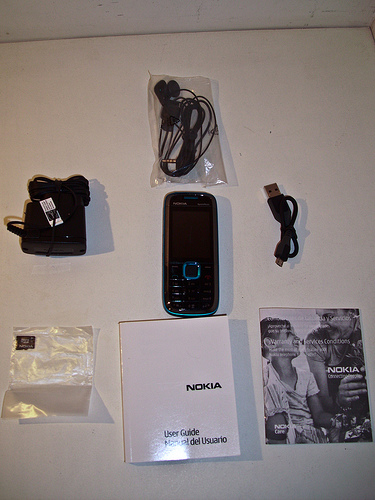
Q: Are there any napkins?
A: No, there are no napkins.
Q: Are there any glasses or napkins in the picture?
A: No, there are no napkins or glasses.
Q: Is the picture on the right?
A: Yes, the picture is on the right of the image.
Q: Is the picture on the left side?
A: No, the picture is on the right of the image.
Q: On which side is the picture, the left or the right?
A: The picture is on the right of the image.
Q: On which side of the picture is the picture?
A: The picture is on the right of the image.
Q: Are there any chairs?
A: No, there are no chairs.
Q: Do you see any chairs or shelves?
A: No, there are no chairs or shelves.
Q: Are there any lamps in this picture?
A: No, there are no lamps.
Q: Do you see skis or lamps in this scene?
A: No, there are no lamps or skis.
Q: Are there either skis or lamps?
A: No, there are no lamps or skis.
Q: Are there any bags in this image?
A: Yes, there is a bag.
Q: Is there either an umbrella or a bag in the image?
A: Yes, there is a bag.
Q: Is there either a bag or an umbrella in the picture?
A: Yes, there is a bag.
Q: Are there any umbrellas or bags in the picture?
A: Yes, there is a bag.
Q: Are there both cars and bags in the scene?
A: No, there is a bag but no cars.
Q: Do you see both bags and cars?
A: No, there is a bag but no cars.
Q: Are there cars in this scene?
A: No, there are no cars.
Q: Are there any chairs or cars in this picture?
A: No, there are no cars or chairs.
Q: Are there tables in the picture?
A: Yes, there is a table.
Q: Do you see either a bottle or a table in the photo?
A: Yes, there is a table.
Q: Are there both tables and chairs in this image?
A: No, there is a table but no chairs.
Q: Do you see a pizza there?
A: No, there are no pizzas.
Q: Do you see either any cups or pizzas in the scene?
A: No, there are no pizzas or cups.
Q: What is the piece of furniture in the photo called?
A: The piece of furniture is a table.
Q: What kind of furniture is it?
A: The piece of furniture is a table.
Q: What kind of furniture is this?
A: This is a table.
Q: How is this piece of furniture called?
A: This is a table.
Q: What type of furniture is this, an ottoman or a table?
A: This is a table.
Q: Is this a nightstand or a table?
A: This is a table.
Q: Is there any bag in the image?
A: Yes, there is a bag.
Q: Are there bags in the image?
A: Yes, there is a bag.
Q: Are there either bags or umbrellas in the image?
A: Yes, there is a bag.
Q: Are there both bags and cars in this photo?
A: No, there is a bag but no cars.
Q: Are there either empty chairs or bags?
A: Yes, there is an empty bag.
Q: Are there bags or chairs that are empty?
A: Yes, the bag is empty.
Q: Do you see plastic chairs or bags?
A: Yes, there is a plastic bag.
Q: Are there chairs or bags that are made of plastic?
A: Yes, the bag is made of plastic.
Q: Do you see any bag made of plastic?
A: Yes, there is a bag that is made of plastic.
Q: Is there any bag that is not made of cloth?
A: Yes, there is a bag that is made of plastic.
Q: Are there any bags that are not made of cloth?
A: Yes, there is a bag that is made of plastic.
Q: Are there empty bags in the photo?
A: Yes, there is an empty bag.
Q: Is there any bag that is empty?
A: Yes, there is an empty bag.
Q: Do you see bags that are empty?
A: Yes, there is an empty bag.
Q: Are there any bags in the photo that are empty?
A: Yes, there is a bag that is empty.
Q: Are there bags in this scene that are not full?
A: Yes, there is a empty bag.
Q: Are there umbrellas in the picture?
A: No, there are no umbrellas.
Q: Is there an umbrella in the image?
A: No, there are no umbrellas.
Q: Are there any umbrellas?
A: No, there are no umbrellas.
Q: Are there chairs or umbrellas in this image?
A: No, there are no umbrellas or chairs.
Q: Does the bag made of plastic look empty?
A: Yes, the bag is empty.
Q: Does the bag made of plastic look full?
A: No, the bag is empty.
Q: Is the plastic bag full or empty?
A: The bag is empty.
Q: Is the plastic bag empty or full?
A: The bag is empty.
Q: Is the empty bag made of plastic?
A: Yes, the bag is made of plastic.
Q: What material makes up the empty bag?
A: The bag is made of plastic.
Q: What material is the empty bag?
A: The bag is made of plastic.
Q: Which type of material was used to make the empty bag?
A: The bag is made of plastic.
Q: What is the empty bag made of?
A: The bag is made of plastic.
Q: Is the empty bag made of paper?
A: No, the bag is made of plastic.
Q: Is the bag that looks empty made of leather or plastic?
A: The bag is made of plastic.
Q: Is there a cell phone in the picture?
A: Yes, there is a cell phone.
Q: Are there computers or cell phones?
A: Yes, there is a cell phone.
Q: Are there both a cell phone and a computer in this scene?
A: No, there is a cell phone but no computers.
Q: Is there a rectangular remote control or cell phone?
A: Yes, there is a rectangular cell phone.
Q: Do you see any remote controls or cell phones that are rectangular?
A: Yes, the cell phone is rectangular.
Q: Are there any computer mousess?
A: No, there are no computer mousess.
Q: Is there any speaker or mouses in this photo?
A: No, there are no computer mousess or speakers.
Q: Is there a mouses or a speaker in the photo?
A: No, there are no computer mousess or speakers.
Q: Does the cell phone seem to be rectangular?
A: Yes, the cell phone is rectangular.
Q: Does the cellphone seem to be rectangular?
A: Yes, the cellphone is rectangular.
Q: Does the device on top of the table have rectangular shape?
A: Yes, the cellphone is rectangular.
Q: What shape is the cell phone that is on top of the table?
A: The cellphone is rectangular.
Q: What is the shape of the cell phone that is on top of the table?
A: The cellphone is rectangular.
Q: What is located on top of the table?
A: The cell phone is on top of the table.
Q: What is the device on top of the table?
A: The device is a cell phone.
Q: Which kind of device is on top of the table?
A: The device is a cell phone.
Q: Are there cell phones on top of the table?
A: Yes, there is a cell phone on top of the table.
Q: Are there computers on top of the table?
A: No, there is a cell phone on top of the table.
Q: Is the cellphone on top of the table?
A: Yes, the cellphone is on top of the table.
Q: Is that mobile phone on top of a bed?
A: No, the mobile phone is on top of the table.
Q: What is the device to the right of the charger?
A: The device is a cell phone.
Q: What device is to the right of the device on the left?
A: The device is a cell phone.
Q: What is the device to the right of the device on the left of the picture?
A: The device is a cell phone.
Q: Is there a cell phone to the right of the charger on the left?
A: Yes, there is a cell phone to the right of the charger.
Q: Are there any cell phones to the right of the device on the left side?
A: Yes, there is a cell phone to the right of the charger.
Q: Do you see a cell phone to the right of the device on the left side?
A: Yes, there is a cell phone to the right of the charger.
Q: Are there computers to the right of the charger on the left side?
A: No, there is a cell phone to the right of the charger.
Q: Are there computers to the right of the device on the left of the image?
A: No, there is a cell phone to the right of the charger.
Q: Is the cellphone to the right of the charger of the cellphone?
A: Yes, the cellphone is to the right of the charger.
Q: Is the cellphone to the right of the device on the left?
A: Yes, the cellphone is to the right of the charger.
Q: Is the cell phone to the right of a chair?
A: No, the cell phone is to the right of the charger.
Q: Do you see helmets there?
A: No, there are no helmets.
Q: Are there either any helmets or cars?
A: No, there are no helmets or cars.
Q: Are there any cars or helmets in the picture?
A: No, there are no helmets or cars.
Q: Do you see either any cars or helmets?
A: No, there are no helmets or cars.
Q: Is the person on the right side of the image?
A: Yes, the person is on the right of the image.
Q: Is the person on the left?
A: No, the person is on the right of the image.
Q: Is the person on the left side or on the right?
A: The person is on the right of the image.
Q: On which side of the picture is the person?
A: The person is on the right of the image.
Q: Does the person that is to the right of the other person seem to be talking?
A: Yes, the person is talking.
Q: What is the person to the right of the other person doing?
A: The person is talking.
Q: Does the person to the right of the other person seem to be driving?
A: No, the person is talking.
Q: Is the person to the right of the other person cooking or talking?
A: The person is talking.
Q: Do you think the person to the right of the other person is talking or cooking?
A: The person is talking.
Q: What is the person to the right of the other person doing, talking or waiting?
A: The person is talking.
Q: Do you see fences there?
A: No, there are no fences.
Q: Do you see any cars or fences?
A: No, there are no fences or cars.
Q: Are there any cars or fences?
A: No, there are no fences or cars.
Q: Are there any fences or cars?
A: No, there are no fences or cars.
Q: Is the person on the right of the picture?
A: Yes, the person is on the right of the image.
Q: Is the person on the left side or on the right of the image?
A: The person is on the right of the image.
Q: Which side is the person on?
A: The person is on the right of the image.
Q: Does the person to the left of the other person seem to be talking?
A: Yes, the person is talking.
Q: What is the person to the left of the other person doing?
A: The person is talking.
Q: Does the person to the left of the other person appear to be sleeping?
A: No, the person is talking.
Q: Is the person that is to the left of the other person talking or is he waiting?
A: The person is talking.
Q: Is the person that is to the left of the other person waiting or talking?
A: The person is talking.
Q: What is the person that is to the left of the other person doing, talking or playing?
A: The person is talking.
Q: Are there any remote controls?
A: No, there are no remote controls.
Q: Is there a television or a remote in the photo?
A: No, there are no remote controls or televisions.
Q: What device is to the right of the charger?
A: The device is a screen.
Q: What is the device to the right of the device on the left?
A: The device is a screen.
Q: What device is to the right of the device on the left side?
A: The device is a screen.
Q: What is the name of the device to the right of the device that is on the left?
A: The device is a screen.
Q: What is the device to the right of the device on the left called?
A: The device is a screen.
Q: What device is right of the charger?
A: The device is a screen.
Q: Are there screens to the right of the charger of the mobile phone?
A: Yes, there is a screen to the right of the charger.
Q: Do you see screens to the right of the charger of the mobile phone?
A: Yes, there is a screen to the right of the charger.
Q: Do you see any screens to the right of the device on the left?
A: Yes, there is a screen to the right of the charger.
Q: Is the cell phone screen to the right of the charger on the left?
A: Yes, the screen is to the right of the charger.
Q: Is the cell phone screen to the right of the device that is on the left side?
A: Yes, the screen is to the right of the charger.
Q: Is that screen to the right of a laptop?
A: No, the screen is to the right of the charger.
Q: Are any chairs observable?
A: No, there are no chairs.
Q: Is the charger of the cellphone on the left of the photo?
A: Yes, the charger is on the left of the image.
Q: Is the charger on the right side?
A: No, the charger is on the left of the image.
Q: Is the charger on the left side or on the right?
A: The charger is on the left of the image.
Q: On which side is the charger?
A: The charger is on the left of the image.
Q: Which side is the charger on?
A: The charger is on the left of the image.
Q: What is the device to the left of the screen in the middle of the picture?
A: The device is a charger.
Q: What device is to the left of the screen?
A: The device is a charger.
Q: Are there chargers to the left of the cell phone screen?
A: Yes, there is a charger to the left of the screen.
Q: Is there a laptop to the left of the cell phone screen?
A: No, there is a charger to the left of the screen.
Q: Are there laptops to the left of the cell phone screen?
A: No, there is a charger to the left of the screen.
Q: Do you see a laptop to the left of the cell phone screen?
A: No, there is a charger to the left of the screen.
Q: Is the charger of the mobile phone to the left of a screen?
A: Yes, the charger is to the left of a screen.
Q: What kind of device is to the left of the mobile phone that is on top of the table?
A: The device is a charger.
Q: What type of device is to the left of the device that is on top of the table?
A: The device is a charger.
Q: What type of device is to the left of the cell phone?
A: The device is a charger.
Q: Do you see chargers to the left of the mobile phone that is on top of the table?
A: Yes, there is a charger to the left of the cellphone.